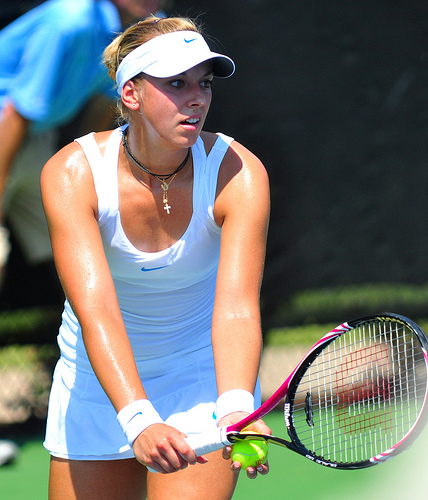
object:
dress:
[41, 124, 265, 461]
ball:
[216, 423, 285, 489]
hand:
[120, 395, 208, 482]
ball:
[228, 431, 267, 470]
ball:
[218, 422, 274, 466]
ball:
[226, 429, 273, 464]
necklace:
[124, 125, 189, 215]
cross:
[162, 203, 171, 215]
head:
[277, 309, 427, 474]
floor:
[276, 454, 425, 498]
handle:
[146, 422, 234, 476]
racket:
[149, 310, 428, 470]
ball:
[227, 426, 267, 471]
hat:
[116, 29, 236, 94]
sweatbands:
[116, 397, 166, 445]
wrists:
[114, 395, 166, 439]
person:
[0, 0, 167, 461]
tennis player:
[38, 13, 273, 500]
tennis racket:
[147, 309, 427, 474]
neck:
[126, 125, 191, 190]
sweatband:
[213, 387, 254, 423]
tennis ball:
[230, 437, 270, 469]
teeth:
[186, 116, 200, 124]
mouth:
[179, 113, 203, 131]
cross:
[154, 199, 178, 215]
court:
[13, 350, 412, 497]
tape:
[143, 426, 233, 474]